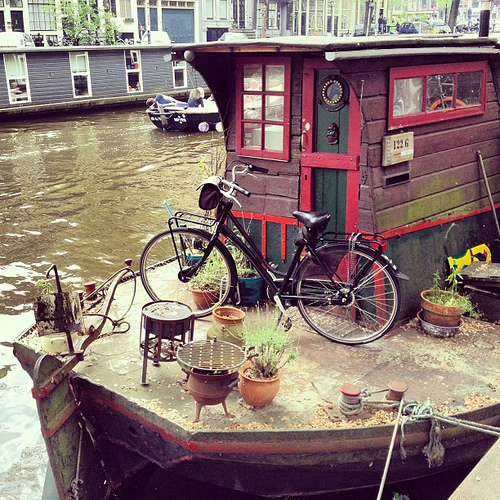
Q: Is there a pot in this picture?
A: Yes, there is a pot.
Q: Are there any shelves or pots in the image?
A: Yes, there is a pot.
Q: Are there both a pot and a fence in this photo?
A: No, there is a pot but no fences.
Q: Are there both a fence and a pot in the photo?
A: No, there is a pot but no fences.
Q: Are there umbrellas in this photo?
A: No, there are no umbrellas.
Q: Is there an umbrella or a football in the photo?
A: No, there are no umbrellas or footballs.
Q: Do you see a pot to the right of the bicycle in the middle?
A: Yes, there is a pot to the right of the bicycle.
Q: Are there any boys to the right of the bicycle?
A: No, there is a pot to the right of the bicycle.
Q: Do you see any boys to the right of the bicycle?
A: No, there is a pot to the right of the bicycle.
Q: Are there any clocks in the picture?
A: No, there are no clocks.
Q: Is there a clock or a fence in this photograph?
A: No, there are no clocks or fences.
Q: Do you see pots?
A: Yes, there is a pot.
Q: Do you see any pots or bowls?
A: Yes, there is a pot.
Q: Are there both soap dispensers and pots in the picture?
A: No, there is a pot but no soap dispensers.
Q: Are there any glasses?
A: No, there are no glasses.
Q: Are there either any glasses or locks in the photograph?
A: No, there are no glasses or locks.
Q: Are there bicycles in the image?
A: Yes, there is a bicycle.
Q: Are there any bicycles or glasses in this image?
A: Yes, there is a bicycle.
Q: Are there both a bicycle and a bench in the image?
A: No, there is a bicycle but no benches.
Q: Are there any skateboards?
A: No, there are no skateboards.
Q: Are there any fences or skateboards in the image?
A: No, there are no skateboards or fences.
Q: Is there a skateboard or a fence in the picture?
A: No, there are no skateboards or fences.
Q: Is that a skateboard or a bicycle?
A: That is a bicycle.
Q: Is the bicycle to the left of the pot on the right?
A: Yes, the bicycle is to the left of the pot.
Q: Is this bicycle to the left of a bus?
A: No, the bicycle is to the left of the pot.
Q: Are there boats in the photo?
A: Yes, there is a boat.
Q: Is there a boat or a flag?
A: Yes, there is a boat.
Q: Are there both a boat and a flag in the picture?
A: No, there is a boat but no flags.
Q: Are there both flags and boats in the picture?
A: No, there is a boat but no flags.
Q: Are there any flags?
A: No, there are no flags.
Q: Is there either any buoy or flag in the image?
A: No, there are no flags or buoys.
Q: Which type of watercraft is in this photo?
A: The watercraft is a boat.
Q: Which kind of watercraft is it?
A: The watercraft is a boat.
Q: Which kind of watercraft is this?
A: This is a boat.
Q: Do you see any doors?
A: Yes, there is a door.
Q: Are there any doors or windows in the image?
A: Yes, there is a door.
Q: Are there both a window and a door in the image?
A: Yes, there are both a door and a window.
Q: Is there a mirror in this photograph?
A: No, there are no mirrors.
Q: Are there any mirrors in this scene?
A: No, there are no mirrors.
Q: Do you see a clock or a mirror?
A: No, there are no mirrors or clocks.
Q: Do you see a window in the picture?
A: Yes, there is a window.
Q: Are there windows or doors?
A: Yes, there is a window.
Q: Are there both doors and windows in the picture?
A: Yes, there are both a window and a door.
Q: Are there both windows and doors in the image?
A: Yes, there are both a window and a door.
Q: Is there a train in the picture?
A: No, there are no trains.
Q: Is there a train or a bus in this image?
A: No, there are no trains or buses.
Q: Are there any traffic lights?
A: No, there are no traffic lights.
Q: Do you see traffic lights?
A: No, there are no traffic lights.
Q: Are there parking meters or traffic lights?
A: No, there are no traffic lights or parking meters.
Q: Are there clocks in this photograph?
A: No, there are no clocks.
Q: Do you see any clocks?
A: No, there are no clocks.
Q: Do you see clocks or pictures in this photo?
A: No, there are no clocks or pictures.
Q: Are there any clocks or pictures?
A: No, there are no clocks or pictures.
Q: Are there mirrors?
A: No, there are no mirrors.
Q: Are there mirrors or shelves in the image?
A: No, there are no mirrors or shelves.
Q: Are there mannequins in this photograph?
A: No, there are no mannequins.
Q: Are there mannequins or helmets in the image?
A: No, there are no mannequins or helmets.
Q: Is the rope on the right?
A: Yes, the rope is on the right of the image.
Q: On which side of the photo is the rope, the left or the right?
A: The rope is on the right of the image.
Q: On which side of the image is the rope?
A: The rope is on the right of the image.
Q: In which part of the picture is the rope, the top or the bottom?
A: The rope is in the bottom of the image.